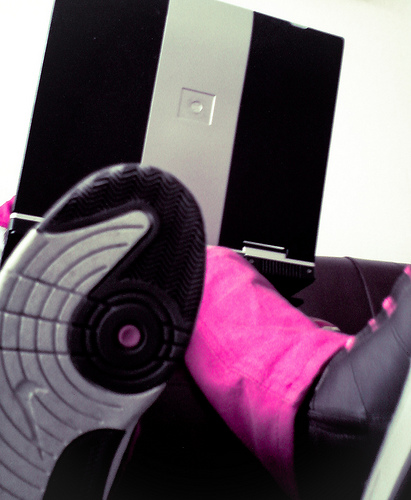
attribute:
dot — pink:
[117, 324, 141, 348]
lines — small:
[0, 466, 45, 498]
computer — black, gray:
[83, 17, 328, 253]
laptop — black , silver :
[0, 1, 344, 296]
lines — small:
[55, 224, 147, 265]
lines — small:
[15, 260, 56, 459]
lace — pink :
[402, 266, 409, 277]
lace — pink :
[343, 333, 358, 354]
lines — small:
[4, 269, 92, 366]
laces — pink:
[341, 294, 398, 353]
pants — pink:
[185, 247, 351, 498]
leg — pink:
[179, 240, 363, 498]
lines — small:
[2, 219, 142, 494]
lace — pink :
[382, 294, 393, 311]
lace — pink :
[357, 284, 409, 332]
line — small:
[37, 358, 102, 426]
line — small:
[6, 276, 46, 316]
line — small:
[72, 256, 105, 291]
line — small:
[21, 262, 69, 302]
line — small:
[6, 297, 81, 344]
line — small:
[13, 334, 92, 373]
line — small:
[101, 289, 178, 339]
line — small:
[73, 304, 177, 361]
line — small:
[73, 339, 172, 380]